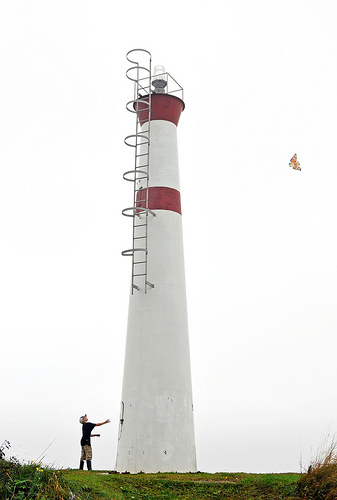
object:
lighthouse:
[115, 43, 198, 477]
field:
[0, 468, 337, 499]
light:
[151, 77, 168, 93]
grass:
[105, 474, 241, 495]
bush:
[294, 447, 337, 498]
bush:
[0, 442, 35, 497]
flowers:
[224, 472, 230, 481]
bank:
[1, 463, 336, 498]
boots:
[86, 459, 91, 471]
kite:
[289, 153, 301, 171]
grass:
[18, 471, 134, 496]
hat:
[79, 414, 86, 424]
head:
[79, 413, 89, 424]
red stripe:
[136, 186, 185, 215]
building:
[114, 46, 197, 474]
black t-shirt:
[80, 422, 96, 446]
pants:
[79, 444, 93, 464]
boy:
[79, 412, 110, 470]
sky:
[269, 37, 335, 94]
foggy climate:
[216, 39, 283, 138]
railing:
[143, 49, 152, 291]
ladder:
[121, 45, 156, 296]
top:
[132, 92, 185, 126]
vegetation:
[0, 440, 80, 498]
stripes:
[131, 93, 185, 126]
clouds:
[235, 20, 334, 130]